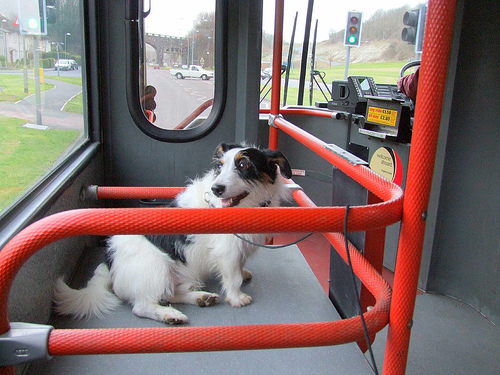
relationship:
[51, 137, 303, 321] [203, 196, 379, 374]
dog wears leash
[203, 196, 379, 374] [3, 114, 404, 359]
leash over handrail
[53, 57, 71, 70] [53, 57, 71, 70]
car close to car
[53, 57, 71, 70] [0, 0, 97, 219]
car through window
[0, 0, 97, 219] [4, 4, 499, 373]
window on bus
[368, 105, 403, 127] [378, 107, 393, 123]
sticker explains fares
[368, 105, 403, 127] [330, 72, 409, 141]
sticker on farebox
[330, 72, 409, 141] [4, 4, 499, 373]
farebox on bus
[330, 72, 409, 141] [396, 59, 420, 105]
farebox next to driver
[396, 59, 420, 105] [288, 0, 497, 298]
driver sits on right of bus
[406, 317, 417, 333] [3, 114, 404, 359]
bolt on handrail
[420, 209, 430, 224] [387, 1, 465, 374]
bolt on post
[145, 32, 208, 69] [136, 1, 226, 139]
bridge through window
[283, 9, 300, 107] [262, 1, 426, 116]
wiper on windshield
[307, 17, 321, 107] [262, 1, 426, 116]
wiper on windshield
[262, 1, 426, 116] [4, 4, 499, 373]
windshield on bus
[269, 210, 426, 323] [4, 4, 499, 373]
floor of bus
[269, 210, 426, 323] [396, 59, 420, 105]
floor beside driver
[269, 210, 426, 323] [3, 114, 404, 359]
floor matches handrail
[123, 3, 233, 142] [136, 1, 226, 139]
rubber around window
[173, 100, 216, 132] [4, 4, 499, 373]
railing on bus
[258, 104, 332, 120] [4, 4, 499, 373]
railing on bus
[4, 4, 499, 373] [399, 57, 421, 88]
bus has steering wheel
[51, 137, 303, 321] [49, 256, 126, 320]
dog has tail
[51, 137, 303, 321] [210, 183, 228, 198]
dog has nose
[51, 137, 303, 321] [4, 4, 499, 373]
dog in bus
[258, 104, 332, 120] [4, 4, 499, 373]
railing inside bus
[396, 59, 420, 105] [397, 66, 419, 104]
driver has arm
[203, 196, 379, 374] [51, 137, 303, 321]
leash around dog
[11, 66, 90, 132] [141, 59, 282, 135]
sidewalk next to road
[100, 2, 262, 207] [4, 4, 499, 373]
door into bus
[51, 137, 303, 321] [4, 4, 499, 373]
dog on bus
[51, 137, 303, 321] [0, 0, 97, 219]
dog looks out of window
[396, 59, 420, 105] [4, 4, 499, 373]
driver drives bus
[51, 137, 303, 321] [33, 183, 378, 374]
dog on seat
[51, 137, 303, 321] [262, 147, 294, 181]
dog has ear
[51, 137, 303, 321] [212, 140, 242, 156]
dog has ear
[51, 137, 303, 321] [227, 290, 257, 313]
dog has paw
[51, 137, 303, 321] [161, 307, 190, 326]
dog has paw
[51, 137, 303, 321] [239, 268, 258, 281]
dog has paw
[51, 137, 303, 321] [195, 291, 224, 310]
dog has paw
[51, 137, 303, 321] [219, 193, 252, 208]
dog has mouth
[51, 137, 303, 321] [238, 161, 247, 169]
dog has eye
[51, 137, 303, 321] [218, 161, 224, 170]
dog has eye